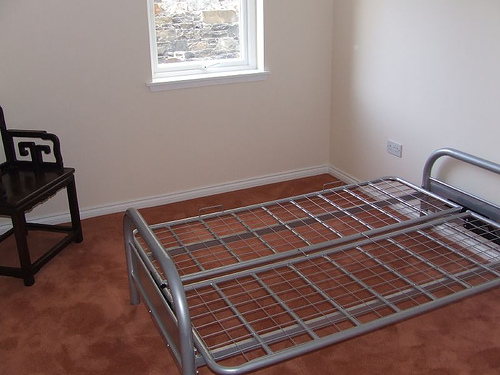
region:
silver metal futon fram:
[102, 143, 496, 373]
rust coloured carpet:
[0, 170, 497, 373]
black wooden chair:
[0, 114, 91, 290]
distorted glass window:
[138, 0, 281, 97]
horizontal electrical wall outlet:
[379, 129, 413, 162]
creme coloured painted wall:
[324, 0, 499, 264]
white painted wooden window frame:
[133, 0, 280, 100]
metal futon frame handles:
[194, 173, 353, 223]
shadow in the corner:
[328, 2, 355, 178]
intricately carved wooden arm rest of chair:
[2, 123, 64, 173]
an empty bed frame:
[141, 158, 431, 354]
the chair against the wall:
[2, 78, 97, 278]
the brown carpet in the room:
[60, 323, 141, 369]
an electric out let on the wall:
[373, 130, 424, 176]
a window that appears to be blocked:
[121, 0, 297, 80]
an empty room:
[10, 4, 449, 278]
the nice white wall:
[383, 26, 444, 62]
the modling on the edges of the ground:
[116, 173, 243, 208]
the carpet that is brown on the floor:
[41, 303, 113, 345]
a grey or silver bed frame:
[130, 199, 495, 310]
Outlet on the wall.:
[381, 136, 405, 159]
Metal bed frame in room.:
[119, 148, 498, 373]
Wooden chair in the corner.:
[0, 103, 92, 290]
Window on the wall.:
[131, 2, 286, 97]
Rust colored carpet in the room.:
[1, 168, 498, 370]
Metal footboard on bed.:
[120, 198, 205, 373]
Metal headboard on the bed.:
[419, 141, 499, 238]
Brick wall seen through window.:
[151, 2, 253, 68]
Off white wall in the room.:
[3, 3, 499, 252]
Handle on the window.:
[198, 58, 226, 75]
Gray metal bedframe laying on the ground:
[112, 147, 487, 367]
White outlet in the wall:
[365, 125, 411, 165]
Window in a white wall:
[135, 0, 270, 80]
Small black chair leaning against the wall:
[0, 112, 95, 267]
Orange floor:
[53, 284, 135, 361]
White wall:
[50, 31, 145, 136]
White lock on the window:
[180, 53, 237, 70]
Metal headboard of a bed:
[428, 130, 495, 192]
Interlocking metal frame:
[220, 277, 339, 314]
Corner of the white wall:
[314, 15, 347, 171]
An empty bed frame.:
[130, 163, 497, 365]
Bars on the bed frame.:
[185, 221, 349, 338]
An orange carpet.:
[20, 319, 138, 373]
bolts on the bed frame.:
[145, 302, 170, 350]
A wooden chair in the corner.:
[0, 104, 82, 287]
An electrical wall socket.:
[385, 136, 404, 158]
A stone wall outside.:
[162, 8, 236, 53]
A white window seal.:
[148, 65, 270, 90]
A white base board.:
[182, 162, 361, 202]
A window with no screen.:
[141, 1, 273, 93]